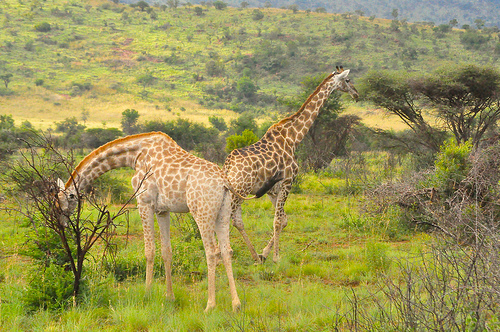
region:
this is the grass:
[262, 285, 300, 317]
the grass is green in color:
[263, 285, 308, 316]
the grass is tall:
[251, 287, 297, 320]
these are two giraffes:
[50, 58, 362, 305]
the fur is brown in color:
[148, 157, 188, 184]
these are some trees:
[358, 65, 499, 179]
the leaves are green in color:
[363, 71, 402, 93]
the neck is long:
[276, 83, 336, 146]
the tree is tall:
[380, 70, 490, 178]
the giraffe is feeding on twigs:
[49, 170, 89, 234]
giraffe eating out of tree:
[34, 132, 242, 297]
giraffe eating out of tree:
[239, 70, 362, 264]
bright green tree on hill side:
[122, 107, 144, 124]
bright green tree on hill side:
[136, 71, 157, 91]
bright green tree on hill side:
[256, 50, 284, 72]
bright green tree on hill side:
[21, 70, 48, 90]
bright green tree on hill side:
[161, 49, 181, 69]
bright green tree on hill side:
[199, 59, 228, 77]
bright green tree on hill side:
[271, 30, 301, 60]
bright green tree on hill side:
[398, 45, 420, 61]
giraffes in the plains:
[43, 54, 373, 325]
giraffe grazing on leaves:
[9, 130, 249, 321]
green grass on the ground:
[241, 282, 338, 325]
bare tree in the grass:
[369, 253, 498, 323]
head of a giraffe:
[327, 52, 364, 112]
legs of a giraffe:
[130, 214, 255, 312]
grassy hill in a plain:
[20, 0, 359, 72]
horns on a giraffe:
[333, 62, 346, 73]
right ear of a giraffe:
[54, 174, 67, 192]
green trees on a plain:
[361, 57, 498, 151]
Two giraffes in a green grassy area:
[18, 22, 460, 326]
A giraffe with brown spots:
[221, 55, 368, 261]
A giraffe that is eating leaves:
[18, 123, 250, 325]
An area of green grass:
[291, 219, 372, 289]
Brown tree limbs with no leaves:
[378, 255, 499, 330]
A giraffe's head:
[330, 59, 363, 100]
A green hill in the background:
[31, 17, 293, 107]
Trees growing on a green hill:
[378, 4, 490, 61]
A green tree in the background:
[358, 46, 496, 138]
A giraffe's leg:
[194, 215, 225, 315]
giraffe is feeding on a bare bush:
[31, 122, 256, 319]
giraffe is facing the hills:
[216, 56, 366, 273]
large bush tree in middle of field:
[355, 51, 499, 159]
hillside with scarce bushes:
[1, 1, 493, 160]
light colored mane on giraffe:
[61, 126, 178, 191]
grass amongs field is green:
[1, 176, 495, 330]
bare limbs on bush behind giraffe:
[318, 206, 498, 331]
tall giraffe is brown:
[213, 61, 365, 265]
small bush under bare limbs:
[17, 257, 79, 315]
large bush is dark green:
[349, 56, 499, 182]